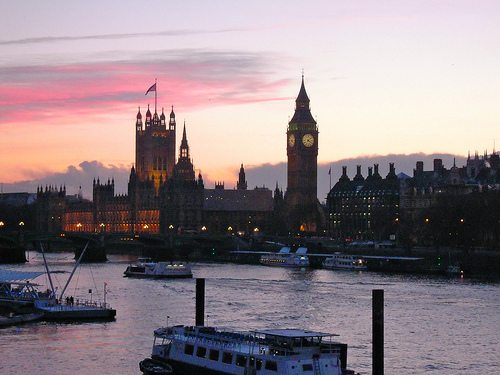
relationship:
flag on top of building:
[145, 82, 155, 95] [128, 77, 177, 201]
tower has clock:
[286, 68, 318, 207] [303, 132, 316, 146]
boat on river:
[124, 256, 193, 279] [2, 246, 500, 373]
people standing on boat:
[66, 295, 74, 305] [36, 283, 117, 324]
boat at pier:
[322, 254, 367, 272] [197, 249, 462, 280]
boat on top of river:
[124, 256, 193, 279] [2, 246, 500, 373]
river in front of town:
[2, 246, 500, 373] [1, 73, 497, 282]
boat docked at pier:
[262, 251, 310, 268] [197, 249, 462, 280]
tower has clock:
[286, 68, 318, 207] [288, 135, 296, 145]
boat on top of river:
[132, 280, 383, 375] [2, 246, 500, 373]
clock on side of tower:
[303, 132, 316, 146] [286, 68, 318, 207]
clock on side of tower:
[288, 135, 296, 145] [286, 68, 318, 207]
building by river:
[128, 77, 177, 201] [2, 246, 500, 373]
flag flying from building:
[145, 82, 155, 95] [128, 77, 177, 201]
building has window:
[128, 77, 177, 201] [152, 160, 159, 170]